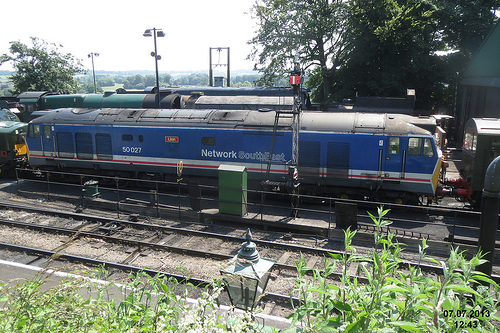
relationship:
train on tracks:
[23, 107, 453, 189] [9, 185, 462, 313]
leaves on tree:
[332, 268, 475, 313] [6, 32, 81, 90]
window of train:
[43, 125, 50, 139] [23, 107, 453, 189]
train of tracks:
[4, 71, 481, 253] [4, 170, 483, 295]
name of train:
[196, 143, 248, 161] [4, 71, 481, 253]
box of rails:
[215, 162, 254, 220] [0, 201, 500, 310]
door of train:
[322, 126, 362, 201] [5, 86, 482, 244]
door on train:
[326, 141, 351, 180] [2, 68, 478, 229]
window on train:
[406, 136, 422, 157] [5, 86, 482, 244]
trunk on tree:
[351, 70, 395, 105] [5, 39, 88, 84]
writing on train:
[116, 135, 234, 158] [5, 86, 482, 244]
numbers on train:
[117, 140, 143, 156] [4, 71, 481, 253]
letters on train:
[195, 145, 241, 161] [4, 71, 481, 253]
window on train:
[406, 136, 422, 157] [4, 71, 481, 253]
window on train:
[53, 131, 75, 162] [13, 95, 449, 213]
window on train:
[72, 134, 93, 161] [13, 95, 449, 213]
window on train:
[97, 130, 122, 164] [15, 101, 453, 224]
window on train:
[297, 141, 324, 184] [13, 95, 449, 213]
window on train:
[384, 130, 405, 170] [13, 95, 449, 213]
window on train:
[406, 136, 422, 157] [15, 106, 451, 215]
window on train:
[404, 134, 422, 159] [15, 101, 453, 224]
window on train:
[421, 135, 439, 169] [13, 95, 449, 213]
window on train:
[21, 123, 48, 144] [21, 92, 446, 221]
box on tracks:
[217, 163, 247, 216] [36, 187, 300, 248]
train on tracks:
[23, 107, 453, 189] [41, 196, 315, 287]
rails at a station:
[4, 184, 491, 300] [0, 0, 497, 333]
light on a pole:
[137, 20, 169, 49] [150, 27, 162, 88]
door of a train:
[326, 141, 351, 180] [15, 101, 453, 224]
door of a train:
[295, 136, 320, 201] [15, 101, 453, 224]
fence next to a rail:
[4, 138, 249, 230] [1, 194, 495, 306]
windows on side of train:
[115, 127, 224, 156] [1, 78, 450, 228]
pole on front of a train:
[282, 62, 307, 200] [4, 91, 498, 212]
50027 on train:
[115, 145, 155, 165] [15, 101, 453, 224]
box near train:
[217, 163, 247, 216] [13, 95, 449, 213]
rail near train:
[1, 185, 481, 330] [6, 93, 493, 234]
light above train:
[284, 67, 307, 90] [6, 93, 493, 234]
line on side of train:
[27, 150, 432, 185] [2, 84, 492, 224]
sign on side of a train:
[155, 127, 184, 147] [6, 93, 493, 234]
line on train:
[22, 147, 432, 188] [6, 87, 456, 219]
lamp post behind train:
[141, 24, 173, 94] [2, 84, 492, 224]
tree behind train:
[250, 0, 497, 136] [1, 78, 450, 228]